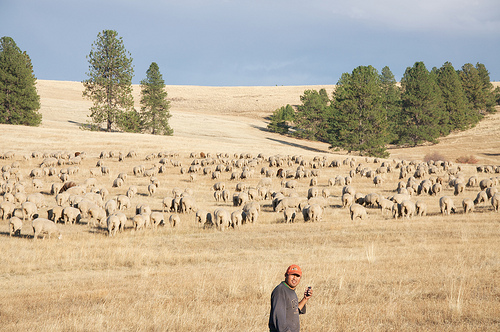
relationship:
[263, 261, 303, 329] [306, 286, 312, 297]
man holding cellphone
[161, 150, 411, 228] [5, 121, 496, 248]
sheep in field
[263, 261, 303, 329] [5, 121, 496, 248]
man in field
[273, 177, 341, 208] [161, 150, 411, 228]
heard of sheep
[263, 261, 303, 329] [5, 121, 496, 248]
man on field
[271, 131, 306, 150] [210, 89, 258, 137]
shadow on ground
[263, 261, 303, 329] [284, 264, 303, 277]
man wearing cap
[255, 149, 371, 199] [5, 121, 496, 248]
flock on field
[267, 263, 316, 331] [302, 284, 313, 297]
man holding cellphone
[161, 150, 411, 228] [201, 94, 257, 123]
sheep eating grass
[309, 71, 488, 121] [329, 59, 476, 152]
trees in group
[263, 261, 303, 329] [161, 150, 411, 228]
man watching sheep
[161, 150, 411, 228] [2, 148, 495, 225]
sheep in cluster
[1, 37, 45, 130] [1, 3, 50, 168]
tree on side